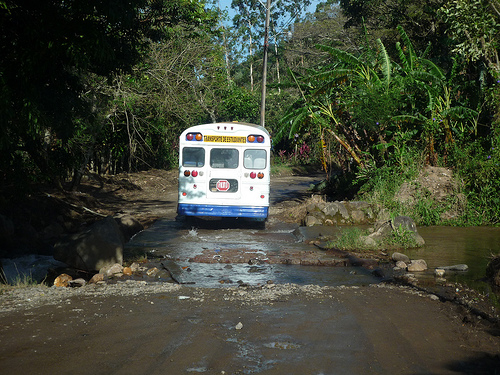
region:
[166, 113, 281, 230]
a white bus on a creek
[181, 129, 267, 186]
red lights on back the bus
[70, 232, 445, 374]
stones on a creek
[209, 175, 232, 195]
a red sign on back of bus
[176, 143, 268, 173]
three windows on back the bus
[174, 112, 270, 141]
roof of bus is white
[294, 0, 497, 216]
plants on right side of creek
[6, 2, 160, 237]
plants on left side of creek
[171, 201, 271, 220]
bumper of bus is blue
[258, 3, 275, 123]
a big trunk of tree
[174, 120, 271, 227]
a white bus with a blue bumper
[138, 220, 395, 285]
water running across the road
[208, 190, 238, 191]
a red stop sign in the window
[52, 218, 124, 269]
a large gray rock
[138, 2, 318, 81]
blue sky seen through the trees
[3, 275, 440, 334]
sparse gravels on a dirt road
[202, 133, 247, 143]
a yellow sign with black letters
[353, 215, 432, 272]
rocks in the water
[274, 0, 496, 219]
trees on the right side of the road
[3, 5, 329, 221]
trees on the left side of the road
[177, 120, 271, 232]
a white bus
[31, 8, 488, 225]
a white bus in the forest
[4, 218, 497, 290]
a river crossing the raod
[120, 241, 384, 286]
the road washed out by the river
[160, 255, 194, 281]
a board in the raod and river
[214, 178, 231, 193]
stop sign on the bus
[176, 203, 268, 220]
a blue bumper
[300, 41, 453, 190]
trees to the right of the bus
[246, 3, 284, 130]
tall trees ahead of the bus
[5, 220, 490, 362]
brown stream overflowing to road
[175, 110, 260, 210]
bus leaving wet area for dryer ground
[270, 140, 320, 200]
curved path ahead of bus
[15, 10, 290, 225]
tangle of trees and branches on shady side of road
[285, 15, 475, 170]
trees with long curved green leaves on sunny side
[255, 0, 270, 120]
tall thin trunk directly in front of bus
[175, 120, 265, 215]
white bus with blue stripe on bottom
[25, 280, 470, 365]
road on higher elevation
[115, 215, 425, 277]
low road connecting to water on both sides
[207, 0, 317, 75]
wedge of bright blue sky over trees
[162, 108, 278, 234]
A white bus in the foreground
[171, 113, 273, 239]
The back of a bus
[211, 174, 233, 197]
A red sign in the back of the bus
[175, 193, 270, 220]
The bottom of the bus is blue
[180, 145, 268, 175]
Back of the bus has three windows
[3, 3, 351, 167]
Tall trees in the background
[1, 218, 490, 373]
The ground is wet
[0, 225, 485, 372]
The ground is brown in color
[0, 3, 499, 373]
Photo was taken in the daytime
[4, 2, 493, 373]
Photo was taken outdoors